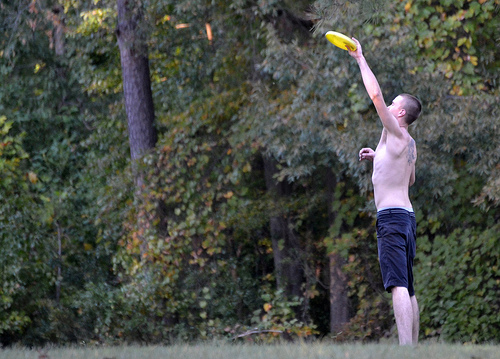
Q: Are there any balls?
A: No, there are no balls.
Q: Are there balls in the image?
A: No, there are no balls.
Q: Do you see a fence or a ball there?
A: No, there are no balls or fences.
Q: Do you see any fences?
A: No, there are no fences.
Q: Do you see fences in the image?
A: No, there are no fences.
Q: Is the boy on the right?
A: Yes, the boy is on the right of the image.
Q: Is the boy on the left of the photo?
A: No, the boy is on the right of the image.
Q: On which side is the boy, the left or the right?
A: The boy is on the right of the image.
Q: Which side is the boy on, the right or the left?
A: The boy is on the right of the image.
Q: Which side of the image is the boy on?
A: The boy is on the right of the image.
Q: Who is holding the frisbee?
A: The boy is holding the frisbee.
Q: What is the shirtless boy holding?
A: The boy is holding the frisbee.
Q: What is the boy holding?
A: The boy is holding the frisbee.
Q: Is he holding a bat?
A: No, the boy is holding the frisbee.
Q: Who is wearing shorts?
A: The boy is wearing shorts.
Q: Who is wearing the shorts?
A: The boy is wearing shorts.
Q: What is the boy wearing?
A: The boy is wearing shorts.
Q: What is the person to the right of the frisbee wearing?
A: The boy is wearing shorts.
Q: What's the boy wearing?
A: The boy is wearing shorts.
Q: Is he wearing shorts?
A: Yes, the boy is wearing shorts.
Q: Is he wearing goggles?
A: No, the boy is wearing shorts.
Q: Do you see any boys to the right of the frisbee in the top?
A: Yes, there is a boy to the right of the frisbee.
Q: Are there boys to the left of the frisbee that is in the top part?
A: No, the boy is to the right of the frisbee.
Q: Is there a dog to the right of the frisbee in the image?
A: No, there is a boy to the right of the frisbee.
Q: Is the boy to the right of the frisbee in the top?
A: Yes, the boy is to the right of the frisbee.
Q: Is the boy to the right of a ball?
A: No, the boy is to the right of the frisbee.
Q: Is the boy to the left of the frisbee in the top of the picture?
A: No, the boy is to the right of the frisbee.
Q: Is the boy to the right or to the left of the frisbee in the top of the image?
A: The boy is to the right of the frisbee.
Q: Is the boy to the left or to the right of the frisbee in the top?
A: The boy is to the right of the frisbee.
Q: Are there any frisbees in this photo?
A: Yes, there is a frisbee.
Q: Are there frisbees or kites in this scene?
A: Yes, there is a frisbee.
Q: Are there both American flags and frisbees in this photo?
A: No, there is a frisbee but no American flags.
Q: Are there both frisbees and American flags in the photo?
A: No, there is a frisbee but no American flags.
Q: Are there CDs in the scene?
A: No, there are no cds.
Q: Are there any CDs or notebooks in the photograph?
A: No, there are no CDs or notebooks.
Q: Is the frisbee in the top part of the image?
A: Yes, the frisbee is in the top of the image.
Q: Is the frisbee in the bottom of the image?
A: No, the frisbee is in the top of the image.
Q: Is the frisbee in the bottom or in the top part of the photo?
A: The frisbee is in the top of the image.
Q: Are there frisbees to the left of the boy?
A: Yes, there is a frisbee to the left of the boy.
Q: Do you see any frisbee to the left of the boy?
A: Yes, there is a frisbee to the left of the boy.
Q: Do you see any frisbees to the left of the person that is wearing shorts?
A: Yes, there is a frisbee to the left of the boy.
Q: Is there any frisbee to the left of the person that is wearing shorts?
A: Yes, there is a frisbee to the left of the boy.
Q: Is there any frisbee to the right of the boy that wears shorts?
A: No, the frisbee is to the left of the boy.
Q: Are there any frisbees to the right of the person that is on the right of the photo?
A: No, the frisbee is to the left of the boy.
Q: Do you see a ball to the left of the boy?
A: No, there is a frisbee to the left of the boy.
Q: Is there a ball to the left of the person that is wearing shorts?
A: No, there is a frisbee to the left of the boy.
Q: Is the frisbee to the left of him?
A: Yes, the frisbee is to the left of a boy.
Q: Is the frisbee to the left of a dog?
A: No, the frisbee is to the left of a boy.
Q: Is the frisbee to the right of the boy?
A: No, the frisbee is to the left of the boy.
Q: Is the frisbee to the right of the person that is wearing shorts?
A: No, the frisbee is to the left of the boy.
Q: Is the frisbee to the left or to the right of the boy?
A: The frisbee is to the left of the boy.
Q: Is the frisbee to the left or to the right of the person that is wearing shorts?
A: The frisbee is to the left of the boy.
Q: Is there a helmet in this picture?
A: No, there are no helmets.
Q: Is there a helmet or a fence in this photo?
A: No, there are no helmets or fences.